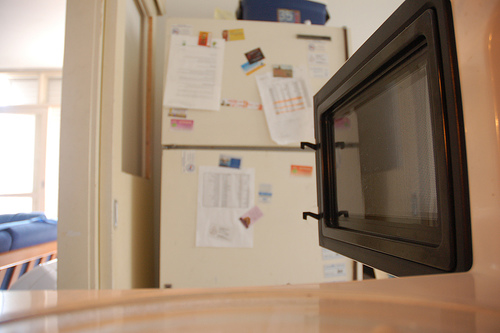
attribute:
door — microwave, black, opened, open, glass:
[295, 2, 476, 283]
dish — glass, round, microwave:
[1, 283, 500, 332]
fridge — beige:
[156, 13, 367, 291]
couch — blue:
[1, 209, 61, 295]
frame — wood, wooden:
[1, 238, 61, 293]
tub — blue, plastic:
[235, 1, 335, 30]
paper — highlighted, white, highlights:
[254, 62, 324, 150]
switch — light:
[112, 199, 122, 227]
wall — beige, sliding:
[96, 1, 167, 292]